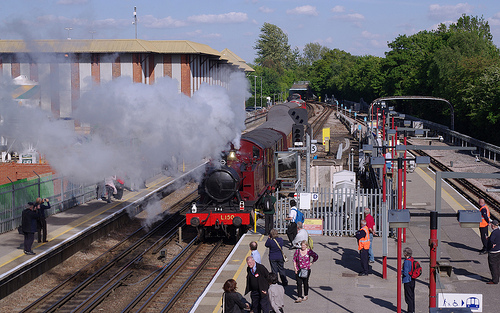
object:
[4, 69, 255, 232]
smoke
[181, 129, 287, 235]
train engine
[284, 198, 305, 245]
people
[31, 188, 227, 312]
train tracks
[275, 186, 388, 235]
fence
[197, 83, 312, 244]
train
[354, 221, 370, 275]
man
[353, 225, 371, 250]
orange vest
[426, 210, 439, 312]
light pole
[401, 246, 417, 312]
man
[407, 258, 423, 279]
backpack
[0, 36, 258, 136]
building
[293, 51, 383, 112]
trees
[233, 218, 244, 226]
bumper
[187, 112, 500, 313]
platform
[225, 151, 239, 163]
bell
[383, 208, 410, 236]
light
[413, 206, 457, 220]
arm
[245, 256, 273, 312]
man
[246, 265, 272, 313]
suit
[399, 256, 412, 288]
shirt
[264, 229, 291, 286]
woman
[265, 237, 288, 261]
shirt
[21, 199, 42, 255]
man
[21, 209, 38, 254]
suit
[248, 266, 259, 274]
shirt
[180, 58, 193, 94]
brick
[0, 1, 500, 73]
clouds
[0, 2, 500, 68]
sky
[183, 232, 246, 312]
stripe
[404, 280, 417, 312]
pants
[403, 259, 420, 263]
shoulders